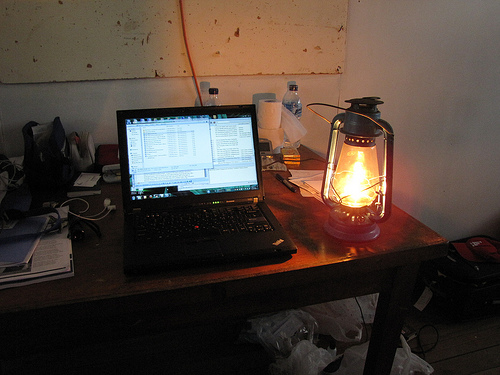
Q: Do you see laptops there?
A: Yes, there is a laptop.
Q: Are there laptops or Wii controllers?
A: Yes, there is a laptop.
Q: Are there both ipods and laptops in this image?
A: No, there is a laptop but no ipods.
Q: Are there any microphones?
A: No, there are no microphones.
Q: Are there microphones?
A: No, there are no microphones.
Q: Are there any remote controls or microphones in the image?
A: No, there are no microphones or remote controls.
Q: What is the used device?
A: The device is a laptop.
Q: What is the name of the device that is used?
A: The device is a laptop.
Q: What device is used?
A: The device is a laptop.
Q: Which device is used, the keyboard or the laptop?
A: The laptop is used.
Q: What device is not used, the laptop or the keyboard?
A: The keyboard is not used.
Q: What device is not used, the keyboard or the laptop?
A: The keyboard is not used.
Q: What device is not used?
A: The device is a keyboard.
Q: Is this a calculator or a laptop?
A: This is a laptop.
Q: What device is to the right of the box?
A: The device is a laptop.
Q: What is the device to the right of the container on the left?
A: The device is a laptop.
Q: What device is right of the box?
A: The device is a laptop.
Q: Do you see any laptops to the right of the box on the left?
A: Yes, there is a laptop to the right of the box.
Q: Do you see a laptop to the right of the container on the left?
A: Yes, there is a laptop to the right of the box.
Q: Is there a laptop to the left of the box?
A: No, the laptop is to the right of the box.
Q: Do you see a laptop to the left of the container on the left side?
A: No, the laptop is to the right of the box.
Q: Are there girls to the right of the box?
A: No, there is a laptop to the right of the box.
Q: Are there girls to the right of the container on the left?
A: No, there is a laptop to the right of the box.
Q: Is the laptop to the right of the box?
A: Yes, the laptop is to the right of the box.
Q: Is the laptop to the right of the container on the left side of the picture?
A: Yes, the laptop is to the right of the box.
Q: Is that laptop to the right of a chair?
A: No, the laptop is to the right of the box.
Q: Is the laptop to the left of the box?
A: No, the laptop is to the right of the box.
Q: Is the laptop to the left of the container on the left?
A: No, the laptop is to the right of the box.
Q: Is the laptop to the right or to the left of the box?
A: The laptop is to the right of the box.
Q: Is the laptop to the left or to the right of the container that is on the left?
A: The laptop is to the right of the box.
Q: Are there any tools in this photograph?
A: No, there are no tools.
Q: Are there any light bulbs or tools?
A: No, there are no tools or light bulbs.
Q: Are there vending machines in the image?
A: No, there are no vending machines.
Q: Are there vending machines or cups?
A: No, there are no vending machines or cups.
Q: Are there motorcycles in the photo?
A: No, there are no motorcycles.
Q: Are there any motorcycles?
A: No, there are no motorcycles.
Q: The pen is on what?
A: The pen is on the table.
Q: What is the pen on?
A: The pen is on the table.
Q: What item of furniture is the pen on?
A: The pen is on the table.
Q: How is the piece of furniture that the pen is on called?
A: The piece of furniture is a table.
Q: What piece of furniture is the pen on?
A: The pen is on the table.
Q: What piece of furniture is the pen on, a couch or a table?
A: The pen is on a table.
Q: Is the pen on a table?
A: Yes, the pen is on a table.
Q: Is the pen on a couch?
A: No, the pen is on a table.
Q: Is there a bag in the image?
A: Yes, there is a bag.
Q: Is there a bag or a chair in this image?
A: Yes, there is a bag.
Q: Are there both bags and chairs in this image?
A: No, there is a bag but no chairs.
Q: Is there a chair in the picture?
A: No, there are no chairs.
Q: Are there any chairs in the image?
A: No, there are no chairs.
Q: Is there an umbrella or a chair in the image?
A: No, there are no chairs or umbrellas.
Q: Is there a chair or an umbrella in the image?
A: No, there are no chairs or umbrellas.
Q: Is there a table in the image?
A: Yes, there is a table.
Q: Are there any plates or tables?
A: Yes, there is a table.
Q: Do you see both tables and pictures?
A: No, there is a table but no pictures.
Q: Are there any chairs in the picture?
A: No, there are no chairs.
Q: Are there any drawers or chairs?
A: No, there are no chairs or drawers.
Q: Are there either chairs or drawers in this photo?
A: No, there are no chairs or drawers.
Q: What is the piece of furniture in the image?
A: The piece of furniture is a table.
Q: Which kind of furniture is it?
A: The piece of furniture is a table.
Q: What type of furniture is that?
A: That is a table.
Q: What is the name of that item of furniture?
A: That is a table.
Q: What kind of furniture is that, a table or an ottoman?
A: That is a table.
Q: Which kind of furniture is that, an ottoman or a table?
A: That is a table.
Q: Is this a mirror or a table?
A: This is a table.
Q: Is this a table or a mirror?
A: This is a table.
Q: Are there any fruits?
A: No, there are no fruits.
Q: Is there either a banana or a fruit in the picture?
A: No, there are no fruits or bananas.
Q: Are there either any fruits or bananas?
A: No, there are no fruits or bananas.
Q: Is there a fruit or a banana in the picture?
A: No, there are no fruits or bananas.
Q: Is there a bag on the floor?
A: Yes, there are bags on the floor.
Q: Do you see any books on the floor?
A: No, there are bags on the floor.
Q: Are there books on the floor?
A: No, there are bags on the floor.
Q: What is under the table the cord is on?
A: The bags are under the table.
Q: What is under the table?
A: The bags are under the table.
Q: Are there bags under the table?
A: Yes, there are bags under the table.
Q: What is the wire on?
A: The wire is on the table.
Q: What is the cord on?
A: The wire is on the table.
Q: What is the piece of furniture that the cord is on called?
A: The piece of furniture is a table.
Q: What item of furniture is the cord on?
A: The cord is on the table.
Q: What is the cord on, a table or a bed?
A: The cord is on a table.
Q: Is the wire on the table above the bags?
A: Yes, the wire is on the table.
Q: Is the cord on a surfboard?
A: No, the cord is on the table.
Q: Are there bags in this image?
A: Yes, there is a bag.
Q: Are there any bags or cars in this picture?
A: Yes, there is a bag.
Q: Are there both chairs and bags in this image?
A: No, there is a bag but no chairs.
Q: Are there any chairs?
A: No, there are no chairs.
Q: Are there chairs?
A: No, there are no chairs.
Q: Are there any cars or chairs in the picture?
A: No, there are no chairs or cars.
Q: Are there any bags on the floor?
A: Yes, there is a bag on the floor.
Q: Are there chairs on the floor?
A: No, there is a bag on the floor.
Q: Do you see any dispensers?
A: No, there are no dispensers.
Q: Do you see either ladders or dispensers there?
A: No, there are no dispensers or ladders.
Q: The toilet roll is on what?
A: The toilet roll is on the table.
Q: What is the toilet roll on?
A: The toilet roll is on the table.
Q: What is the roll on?
A: The toilet roll is on the table.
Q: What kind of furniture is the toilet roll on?
A: The toilet roll is on the table.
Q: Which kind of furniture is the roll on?
A: The toilet roll is on the table.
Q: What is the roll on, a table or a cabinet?
A: The roll is on a table.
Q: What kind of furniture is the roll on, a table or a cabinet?
A: The roll is on a table.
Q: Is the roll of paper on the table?
A: Yes, the roll is on the table.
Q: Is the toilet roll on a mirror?
A: No, the toilet roll is on the table.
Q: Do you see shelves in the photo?
A: No, there are no shelves.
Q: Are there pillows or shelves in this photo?
A: No, there are no shelves or pillows.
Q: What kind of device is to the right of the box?
A: The device is a screen.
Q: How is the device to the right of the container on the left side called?
A: The device is a screen.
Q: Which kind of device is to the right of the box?
A: The device is a screen.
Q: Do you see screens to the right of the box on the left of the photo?
A: Yes, there is a screen to the right of the box.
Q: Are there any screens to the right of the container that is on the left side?
A: Yes, there is a screen to the right of the box.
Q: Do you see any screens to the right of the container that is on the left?
A: Yes, there is a screen to the right of the box.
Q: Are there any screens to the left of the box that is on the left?
A: No, the screen is to the right of the box.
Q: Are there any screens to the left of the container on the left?
A: No, the screen is to the right of the box.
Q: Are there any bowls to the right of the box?
A: No, there is a screen to the right of the box.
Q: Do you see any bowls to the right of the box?
A: No, there is a screen to the right of the box.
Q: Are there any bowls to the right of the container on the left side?
A: No, there is a screen to the right of the box.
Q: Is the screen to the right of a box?
A: Yes, the screen is to the right of a box.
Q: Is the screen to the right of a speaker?
A: No, the screen is to the right of a box.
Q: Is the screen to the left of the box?
A: No, the screen is to the right of the box.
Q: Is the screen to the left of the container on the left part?
A: No, the screen is to the right of the box.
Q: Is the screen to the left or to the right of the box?
A: The screen is to the right of the box.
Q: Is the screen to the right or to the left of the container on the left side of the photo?
A: The screen is to the right of the box.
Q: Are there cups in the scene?
A: No, there are no cups.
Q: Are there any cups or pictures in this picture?
A: No, there are no cups or pictures.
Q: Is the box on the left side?
A: Yes, the box is on the left of the image.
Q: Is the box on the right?
A: No, the box is on the left of the image.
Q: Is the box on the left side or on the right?
A: The box is on the left of the image.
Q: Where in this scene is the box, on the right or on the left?
A: The box is on the left of the image.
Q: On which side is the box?
A: The box is on the left of the image.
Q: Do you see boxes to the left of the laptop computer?
A: Yes, there is a box to the left of the laptop computer.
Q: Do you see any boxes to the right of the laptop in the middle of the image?
A: No, the box is to the left of the laptop.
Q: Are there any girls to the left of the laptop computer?
A: No, there is a box to the left of the laptop computer.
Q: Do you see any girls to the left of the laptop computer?
A: No, there is a box to the left of the laptop computer.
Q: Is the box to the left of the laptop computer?
A: Yes, the box is to the left of the laptop computer.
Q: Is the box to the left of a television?
A: No, the box is to the left of the laptop computer.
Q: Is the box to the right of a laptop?
A: No, the box is to the left of a laptop.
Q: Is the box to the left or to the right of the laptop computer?
A: The box is to the left of the laptop computer.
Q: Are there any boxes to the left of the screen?
A: Yes, there is a box to the left of the screen.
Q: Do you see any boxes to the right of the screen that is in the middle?
A: No, the box is to the left of the screen.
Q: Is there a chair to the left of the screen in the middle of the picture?
A: No, there is a box to the left of the screen.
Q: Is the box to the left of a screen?
A: Yes, the box is to the left of a screen.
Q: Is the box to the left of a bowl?
A: No, the box is to the left of a screen.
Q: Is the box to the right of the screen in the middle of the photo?
A: No, the box is to the left of the screen.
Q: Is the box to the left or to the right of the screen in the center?
A: The box is to the left of the screen.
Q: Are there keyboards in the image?
A: Yes, there is a keyboard.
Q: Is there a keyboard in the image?
A: Yes, there is a keyboard.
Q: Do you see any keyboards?
A: Yes, there is a keyboard.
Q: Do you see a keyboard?
A: Yes, there is a keyboard.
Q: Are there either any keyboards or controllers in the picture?
A: Yes, there is a keyboard.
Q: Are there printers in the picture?
A: No, there are no printers.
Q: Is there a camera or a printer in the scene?
A: No, there are no printers or cameras.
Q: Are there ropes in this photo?
A: No, there are no ropes.